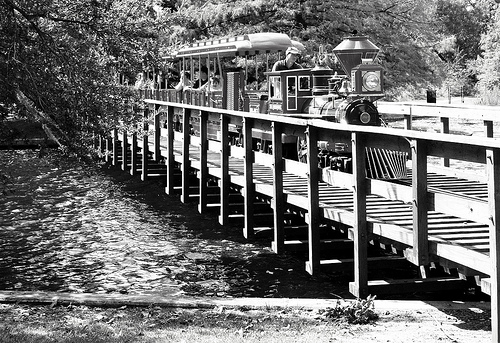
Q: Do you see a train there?
A: Yes, there is a train.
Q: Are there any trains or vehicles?
A: Yes, there is a train.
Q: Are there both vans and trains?
A: No, there is a train but no vans.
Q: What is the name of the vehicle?
A: The vehicle is a train.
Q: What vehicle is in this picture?
A: The vehicle is a train.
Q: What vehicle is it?
A: The vehicle is a train.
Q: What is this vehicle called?
A: This is a train.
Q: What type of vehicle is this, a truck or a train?
A: This is a train.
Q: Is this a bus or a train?
A: This is a train.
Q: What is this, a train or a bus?
A: This is a train.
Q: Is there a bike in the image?
A: No, there are no bikes.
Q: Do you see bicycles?
A: No, there are no bicycles.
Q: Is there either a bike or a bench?
A: No, there are no bikes or benches.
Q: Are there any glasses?
A: No, there are no glasses.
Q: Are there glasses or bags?
A: No, there are no glasses or bags.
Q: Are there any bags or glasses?
A: No, there are no glasses or bags.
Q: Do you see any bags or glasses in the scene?
A: No, there are no glasses or bags.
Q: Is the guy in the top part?
A: Yes, the guy is in the top of the image.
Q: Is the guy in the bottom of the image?
A: No, the guy is in the top of the image.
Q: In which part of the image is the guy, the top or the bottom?
A: The guy is in the top of the image.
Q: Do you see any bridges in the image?
A: Yes, there is a bridge.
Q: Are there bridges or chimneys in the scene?
A: Yes, there is a bridge.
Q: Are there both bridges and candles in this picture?
A: No, there is a bridge but no candles.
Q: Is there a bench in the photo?
A: No, there are no benches.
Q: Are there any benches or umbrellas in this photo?
A: No, there are no benches or umbrellas.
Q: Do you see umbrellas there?
A: No, there are no umbrellas.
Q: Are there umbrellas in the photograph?
A: No, there are no umbrellas.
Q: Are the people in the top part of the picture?
A: Yes, the people are in the top of the image.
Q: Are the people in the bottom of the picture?
A: No, the people are in the top of the image.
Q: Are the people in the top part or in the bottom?
A: The people are in the top of the image.